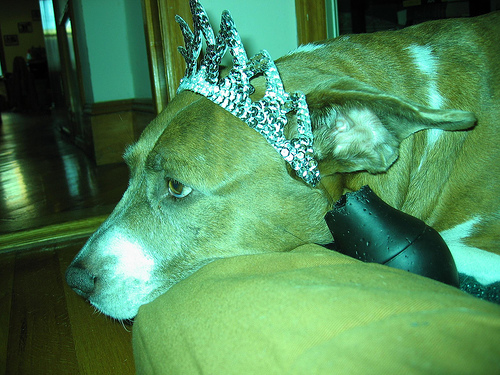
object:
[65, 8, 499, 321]
dog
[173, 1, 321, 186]
tiara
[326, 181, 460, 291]
toy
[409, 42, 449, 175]
patch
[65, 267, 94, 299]
nose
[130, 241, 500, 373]
couch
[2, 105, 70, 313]
floor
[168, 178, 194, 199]
eye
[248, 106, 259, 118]
diamnd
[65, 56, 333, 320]
head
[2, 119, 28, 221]
reflection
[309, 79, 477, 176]
left ear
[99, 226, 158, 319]
patch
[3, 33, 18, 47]
picture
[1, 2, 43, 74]
wall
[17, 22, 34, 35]
picture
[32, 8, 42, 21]
picture